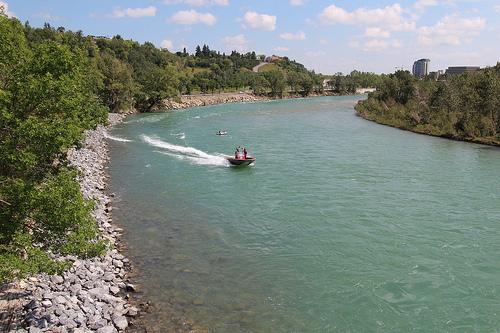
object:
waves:
[123, 139, 132, 142]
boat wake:
[173, 147, 225, 166]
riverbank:
[44, 173, 111, 331]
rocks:
[51, 275, 63, 283]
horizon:
[350, 72, 494, 79]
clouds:
[282, 30, 303, 39]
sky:
[14, 1, 498, 49]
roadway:
[175, 94, 211, 97]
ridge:
[186, 93, 255, 107]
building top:
[445, 66, 486, 74]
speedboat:
[226, 155, 257, 165]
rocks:
[110, 315, 127, 332]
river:
[125, 96, 485, 331]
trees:
[466, 76, 500, 135]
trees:
[287, 70, 299, 99]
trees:
[0, 38, 98, 253]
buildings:
[412, 58, 430, 80]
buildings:
[267, 55, 284, 62]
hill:
[251, 60, 273, 86]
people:
[243, 148, 248, 158]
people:
[219, 131, 220, 133]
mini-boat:
[216, 131, 227, 135]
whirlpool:
[376, 283, 419, 303]